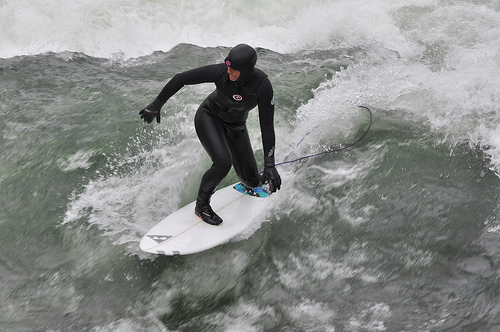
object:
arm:
[149, 64, 221, 110]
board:
[136, 172, 294, 257]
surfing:
[136, 40, 283, 256]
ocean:
[0, 0, 499, 329]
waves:
[0, 0, 499, 332]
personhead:
[224, 42, 258, 83]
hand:
[259, 164, 283, 195]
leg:
[191, 110, 236, 207]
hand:
[136, 104, 164, 125]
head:
[222, 43, 256, 82]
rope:
[256, 105, 373, 174]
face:
[223, 57, 241, 83]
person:
[137, 42, 284, 229]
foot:
[191, 204, 222, 227]